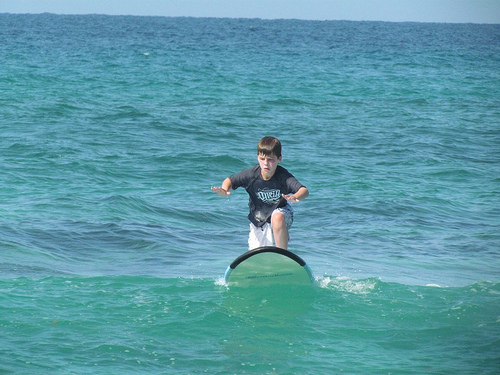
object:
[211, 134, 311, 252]
boy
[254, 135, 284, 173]
head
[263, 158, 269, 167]
nose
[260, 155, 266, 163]
eye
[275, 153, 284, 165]
ear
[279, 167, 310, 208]
arm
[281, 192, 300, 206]
hand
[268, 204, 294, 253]
leg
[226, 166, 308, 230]
t-shirt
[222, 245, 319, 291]
surfboard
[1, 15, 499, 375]
water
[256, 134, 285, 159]
hair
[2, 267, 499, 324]
wave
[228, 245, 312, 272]
border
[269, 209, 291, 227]
knee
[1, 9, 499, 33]
horizon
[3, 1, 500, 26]
sky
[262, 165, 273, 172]
mouth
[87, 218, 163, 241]
ripple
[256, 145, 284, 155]
forehead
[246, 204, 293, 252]
shorts